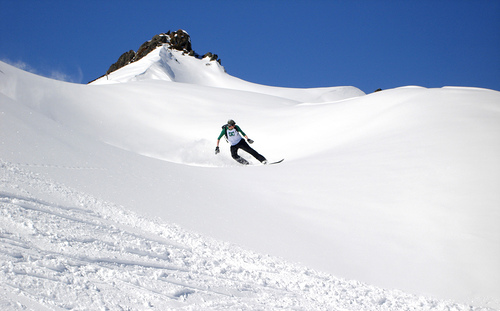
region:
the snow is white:
[82, 73, 409, 274]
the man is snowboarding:
[205, 95, 368, 223]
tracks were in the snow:
[60, 172, 91, 254]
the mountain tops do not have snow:
[114, 33, 249, 92]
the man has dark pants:
[203, 115, 294, 178]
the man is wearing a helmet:
[214, 114, 258, 166]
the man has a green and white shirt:
[205, 124, 283, 149]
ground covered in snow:
[351, 163, 466, 260]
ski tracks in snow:
[45, 242, 202, 295]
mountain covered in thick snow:
[52, 3, 259, 80]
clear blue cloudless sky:
[290, 9, 492, 74]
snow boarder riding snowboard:
[205, 108, 300, 180]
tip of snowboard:
[264, 154, 292, 174]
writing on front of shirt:
[223, 128, 238, 140]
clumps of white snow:
[238, 255, 286, 282]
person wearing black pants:
[226, 135, 263, 170]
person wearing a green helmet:
[223, 117, 237, 128]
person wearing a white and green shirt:
[217, 125, 246, 143]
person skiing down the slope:
[206, 105, 287, 170]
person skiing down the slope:
[198, 103, 288, 170]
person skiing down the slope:
[207, 114, 289, 169]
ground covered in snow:
[100, 136, 254, 276]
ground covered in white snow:
[66, 175, 278, 302]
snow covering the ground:
[15, 156, 231, 304]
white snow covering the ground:
[4, 151, 270, 310]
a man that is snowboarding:
[190, 104, 376, 199]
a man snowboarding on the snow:
[92, 62, 357, 224]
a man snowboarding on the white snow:
[152, 68, 311, 177]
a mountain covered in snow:
[114, 29, 291, 151]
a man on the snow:
[197, 61, 438, 243]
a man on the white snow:
[183, 94, 382, 293]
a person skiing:
[188, 111, 294, 185]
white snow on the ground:
[28, 77, 183, 279]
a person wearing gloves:
[205, 116, 259, 156]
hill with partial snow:
[101, 27, 226, 67]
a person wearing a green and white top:
[201, 110, 259, 152]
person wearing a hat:
[212, 114, 242, 134]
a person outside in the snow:
[202, 111, 289, 186]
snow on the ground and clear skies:
[313, 25, 470, 207]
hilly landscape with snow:
[38, 22, 207, 192]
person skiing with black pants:
[205, 110, 283, 180]